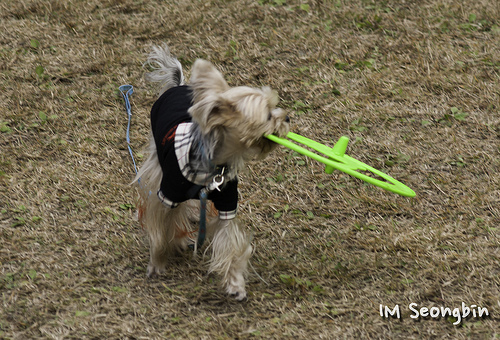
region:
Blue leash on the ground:
[110, 57, 137, 164]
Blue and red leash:
[191, 164, 222, 261]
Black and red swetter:
[141, 79, 267, 237]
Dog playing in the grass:
[123, 35, 269, 330]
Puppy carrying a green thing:
[261, 75, 422, 214]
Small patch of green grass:
[6, 265, 53, 301]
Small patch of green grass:
[67, 270, 140, 327]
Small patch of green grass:
[155, 280, 220, 328]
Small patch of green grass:
[264, 256, 320, 323]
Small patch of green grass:
[267, 188, 339, 236]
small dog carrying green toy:
[118, 59, 295, 313]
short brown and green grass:
[1, 15, 71, 95]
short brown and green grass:
[2, 72, 94, 174]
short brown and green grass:
[24, 151, 69, 228]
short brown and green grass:
[61, 212, 142, 274]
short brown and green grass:
[8, 201, 106, 313]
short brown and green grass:
[257, 199, 327, 283]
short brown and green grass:
[324, 213, 395, 255]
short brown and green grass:
[427, 95, 472, 165]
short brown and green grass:
[308, 49, 398, 117]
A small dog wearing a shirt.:
[126, 47, 291, 302]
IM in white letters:
[376, 303, 401, 320]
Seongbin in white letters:
[407, 302, 488, 325]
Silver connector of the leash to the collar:
[202, 171, 226, 193]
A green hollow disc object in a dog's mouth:
[265, 120, 417, 199]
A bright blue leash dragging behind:
[114, 81, 141, 187]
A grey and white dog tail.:
[141, 43, 183, 97]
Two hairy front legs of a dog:
[144, 187, 252, 301]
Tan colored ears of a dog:
[189, 55, 232, 130]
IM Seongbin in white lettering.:
[376, 300, 489, 327]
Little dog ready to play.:
[132, 56, 386, 305]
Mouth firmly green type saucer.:
[252, 72, 437, 209]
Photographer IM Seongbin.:
[367, 286, 493, 333]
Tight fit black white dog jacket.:
[151, 58, 276, 297]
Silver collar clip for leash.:
[201, 153, 241, 193]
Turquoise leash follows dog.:
[116, 77, 221, 266]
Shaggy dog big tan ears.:
[192, 54, 304, 169]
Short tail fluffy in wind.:
[129, 31, 191, 88]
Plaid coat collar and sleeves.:
[157, 112, 198, 216]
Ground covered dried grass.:
[8, 38, 308, 324]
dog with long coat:
[137, 45, 284, 292]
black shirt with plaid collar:
[149, 86, 243, 217]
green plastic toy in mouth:
[261, 124, 414, 196]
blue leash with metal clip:
[188, 167, 230, 259]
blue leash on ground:
[116, 82, 145, 174]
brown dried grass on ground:
[16, 3, 492, 329]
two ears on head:
[185, 61, 249, 132]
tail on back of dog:
[148, 44, 186, 98]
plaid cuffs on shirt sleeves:
[150, 191, 239, 221]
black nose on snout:
[273, 112, 292, 137]